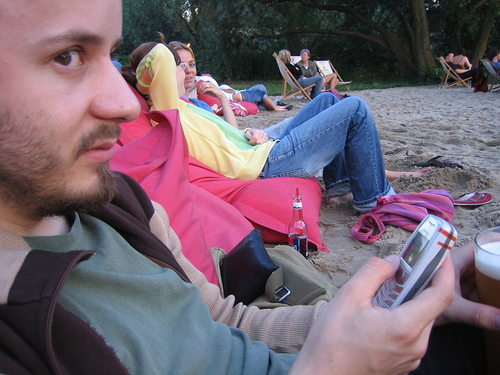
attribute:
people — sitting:
[1, 1, 499, 374]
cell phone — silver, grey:
[372, 214, 457, 306]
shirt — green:
[296, 60, 319, 75]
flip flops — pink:
[328, 88, 339, 97]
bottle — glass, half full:
[289, 190, 308, 260]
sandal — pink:
[449, 191, 493, 206]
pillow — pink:
[186, 158, 326, 251]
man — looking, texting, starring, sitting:
[2, 1, 499, 374]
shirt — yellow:
[135, 43, 278, 181]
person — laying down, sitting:
[201, 80, 291, 112]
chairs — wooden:
[272, 52, 316, 102]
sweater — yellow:
[134, 44, 278, 180]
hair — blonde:
[279, 50, 292, 65]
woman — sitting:
[279, 50, 321, 98]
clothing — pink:
[357, 193, 452, 245]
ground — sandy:
[220, 84, 498, 288]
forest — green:
[121, 4, 497, 81]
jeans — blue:
[263, 94, 396, 211]